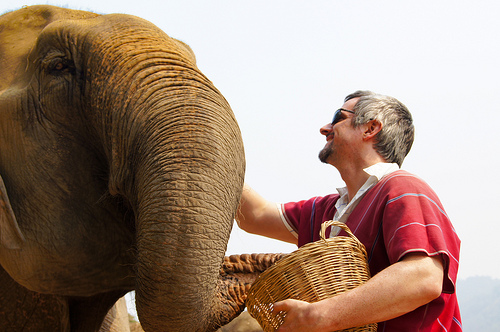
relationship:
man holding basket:
[235, 89, 464, 331] [244, 219, 379, 331]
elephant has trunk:
[0, 3, 290, 330] [101, 28, 290, 330]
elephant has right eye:
[0, 3, 290, 330] [53, 60, 71, 72]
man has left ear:
[235, 89, 464, 331] [362, 118, 384, 142]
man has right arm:
[235, 89, 464, 331] [233, 182, 325, 244]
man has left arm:
[235, 89, 464, 331] [309, 192, 446, 329]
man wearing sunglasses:
[235, 89, 464, 331] [331, 108, 373, 124]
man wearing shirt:
[235, 89, 464, 331] [275, 162, 463, 331]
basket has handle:
[244, 219, 379, 331] [318, 218, 361, 247]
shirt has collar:
[275, 162, 463, 331] [333, 162, 400, 217]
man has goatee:
[235, 89, 464, 331] [318, 139, 334, 164]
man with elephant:
[235, 89, 464, 331] [0, 3, 290, 330]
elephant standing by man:
[0, 3, 290, 330] [235, 89, 464, 331]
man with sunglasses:
[235, 89, 464, 331] [331, 108, 373, 124]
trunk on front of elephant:
[101, 28, 290, 330] [0, 3, 290, 330]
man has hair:
[235, 89, 464, 331] [343, 89, 415, 169]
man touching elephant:
[235, 89, 464, 331] [0, 3, 290, 330]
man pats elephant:
[235, 89, 464, 331] [0, 3, 290, 330]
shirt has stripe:
[275, 162, 463, 331] [382, 192, 457, 233]